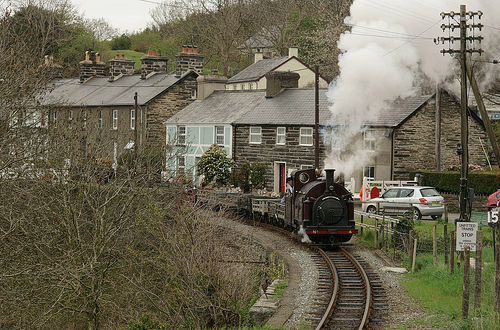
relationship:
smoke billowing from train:
[327, 5, 404, 157] [254, 178, 354, 241]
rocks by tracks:
[294, 253, 319, 309] [249, 216, 385, 326]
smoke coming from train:
[318, 0, 499, 182] [186, 167, 356, 248]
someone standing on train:
[283, 174, 299, 231] [189, 162, 359, 249]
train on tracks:
[257, 167, 359, 253] [180, 192, 381, 326]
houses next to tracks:
[23, 55, 487, 212] [180, 192, 381, 326]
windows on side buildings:
[250, 128, 316, 150] [30, 21, 488, 276]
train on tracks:
[237, 157, 362, 247] [307, 246, 387, 328]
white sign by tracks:
[455, 219, 479, 255] [307, 246, 387, 328]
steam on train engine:
[323, 0, 492, 181] [284, 165, 358, 248]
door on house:
[268, 160, 290, 192] [168, 50, 498, 247]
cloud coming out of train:
[325, 8, 474, 192] [178, 154, 373, 274]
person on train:
[281, 176, 296, 202] [186, 167, 356, 248]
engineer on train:
[284, 175, 296, 201] [207, 161, 359, 258]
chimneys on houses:
[75, 51, 202, 80] [37, 42, 200, 164]